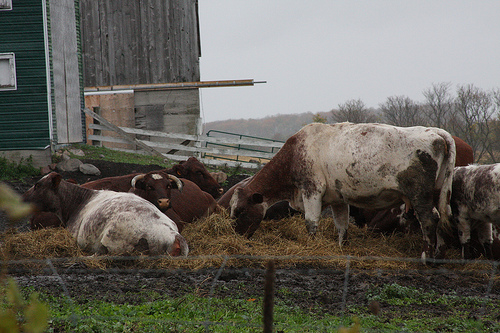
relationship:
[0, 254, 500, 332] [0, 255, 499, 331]
fence has wire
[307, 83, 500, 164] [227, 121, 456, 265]
trees behind cow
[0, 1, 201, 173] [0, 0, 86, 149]
barn has green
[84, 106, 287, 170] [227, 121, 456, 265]
fence around cow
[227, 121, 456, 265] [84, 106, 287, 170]
cow in fence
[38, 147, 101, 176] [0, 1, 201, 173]
rocks near barn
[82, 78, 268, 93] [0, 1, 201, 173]
long object sticking from barn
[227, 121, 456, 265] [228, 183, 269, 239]
cow has a head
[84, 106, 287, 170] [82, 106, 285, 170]
fence has slats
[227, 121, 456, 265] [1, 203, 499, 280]
cow eating hay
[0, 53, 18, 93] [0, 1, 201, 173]
window on barn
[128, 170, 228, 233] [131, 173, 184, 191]
cow has horns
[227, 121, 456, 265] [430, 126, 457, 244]
cow has a tail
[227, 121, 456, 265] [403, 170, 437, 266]
cow has a hind leg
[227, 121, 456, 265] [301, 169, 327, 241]
cow has a front leg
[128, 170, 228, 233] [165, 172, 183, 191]
cow has a horn